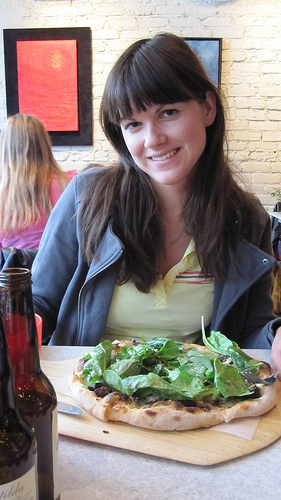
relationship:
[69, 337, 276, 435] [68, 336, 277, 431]
crust of a pizza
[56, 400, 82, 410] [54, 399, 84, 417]
edge of knife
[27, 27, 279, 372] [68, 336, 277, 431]
woman in front of pizza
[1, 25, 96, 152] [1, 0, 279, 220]
picture hung from wall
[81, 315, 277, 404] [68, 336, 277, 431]
spinach on top of pizza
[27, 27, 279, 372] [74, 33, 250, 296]
woman with hair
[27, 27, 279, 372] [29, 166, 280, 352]
woman wearing jacket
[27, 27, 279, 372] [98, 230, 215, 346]
woman wearing shirt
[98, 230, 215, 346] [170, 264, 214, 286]
shirt has stripes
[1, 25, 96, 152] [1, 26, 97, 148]
picture has frame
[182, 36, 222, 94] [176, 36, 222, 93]
picture inside of frame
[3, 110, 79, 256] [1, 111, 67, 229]
woman with hair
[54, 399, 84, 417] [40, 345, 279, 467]
knife on top of board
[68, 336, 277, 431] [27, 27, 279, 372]
pizza in front of woman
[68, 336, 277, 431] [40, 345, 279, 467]
pizza on top of board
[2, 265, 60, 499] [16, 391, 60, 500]
bottle of beer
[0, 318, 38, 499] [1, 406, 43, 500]
bottle of beer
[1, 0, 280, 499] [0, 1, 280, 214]
photo has daylight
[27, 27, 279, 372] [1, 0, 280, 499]
woman in photo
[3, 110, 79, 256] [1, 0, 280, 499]
woman in photo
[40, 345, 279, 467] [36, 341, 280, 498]
board set on top of table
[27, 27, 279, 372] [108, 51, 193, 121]
woman has bangs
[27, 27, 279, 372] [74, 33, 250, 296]
woman has hair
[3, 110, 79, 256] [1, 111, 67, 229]
woman has hair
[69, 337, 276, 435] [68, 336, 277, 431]
crust of pizza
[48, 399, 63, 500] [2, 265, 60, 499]
label placed on bottle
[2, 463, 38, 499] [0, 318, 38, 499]
label placed on bottle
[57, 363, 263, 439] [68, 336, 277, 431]
napkin underneath pizza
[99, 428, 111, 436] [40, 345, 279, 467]
crumb on board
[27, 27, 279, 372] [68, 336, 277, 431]
woman preparing to eat pizza